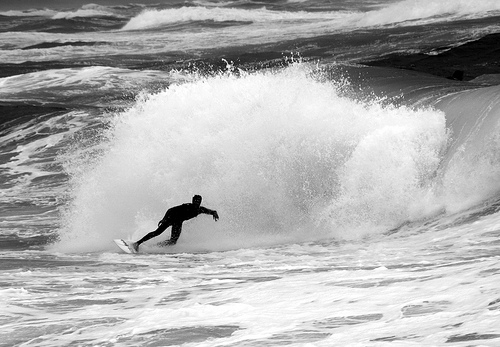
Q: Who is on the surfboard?
A: The man.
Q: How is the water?
A: Wavy.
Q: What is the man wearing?
A: A wetsuit.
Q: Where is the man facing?
A: The shore.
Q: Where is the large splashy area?
A: Behind surfer.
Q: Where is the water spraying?
A: Along side of surfer.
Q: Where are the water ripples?
A: In front of surfer.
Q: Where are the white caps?
A: On water.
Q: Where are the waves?
A: Besides man.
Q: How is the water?
A: Spashy.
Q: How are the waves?
A: Strong.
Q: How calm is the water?
A: Rough.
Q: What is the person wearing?
A: Wetsuit.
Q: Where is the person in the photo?
A: In the ocean.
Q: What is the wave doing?
A: Splashing.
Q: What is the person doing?
A: Surfing.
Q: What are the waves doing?
A: The waves are in motion.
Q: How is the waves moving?
A: Rolling.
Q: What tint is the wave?
A: White.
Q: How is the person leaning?
A: To the right.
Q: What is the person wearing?
A: All black.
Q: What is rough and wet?
A: Ocean.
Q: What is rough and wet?
A: Water.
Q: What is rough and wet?
A: Water.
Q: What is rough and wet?
A: Water.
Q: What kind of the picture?
A: Black and white.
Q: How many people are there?
A: 1.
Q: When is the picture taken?
A: Daytime.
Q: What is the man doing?
A: Wakeboarding.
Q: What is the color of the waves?
A: White.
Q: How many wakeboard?
A: One.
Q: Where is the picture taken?
A: At the ocean.